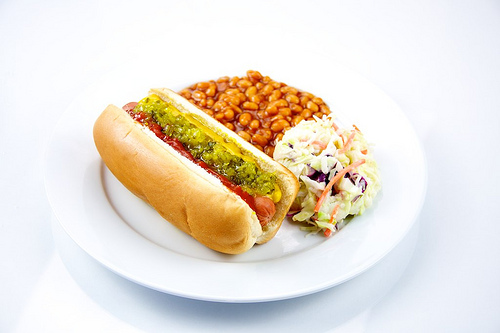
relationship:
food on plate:
[93, 70, 377, 255] [57, 32, 429, 303]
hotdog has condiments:
[92, 85, 299, 255] [135, 94, 282, 201]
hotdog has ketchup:
[92, 85, 299, 255] [134, 112, 255, 207]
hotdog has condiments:
[92, 85, 299, 255] [138, 94, 283, 197]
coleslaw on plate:
[273, 113, 375, 237] [57, 32, 429, 303]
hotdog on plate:
[92, 85, 299, 255] [57, 32, 429, 303]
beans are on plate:
[179, 69, 331, 158] [57, 32, 429, 303]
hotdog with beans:
[92, 85, 299, 255] [179, 69, 331, 158]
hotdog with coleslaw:
[92, 85, 299, 255] [273, 113, 375, 237]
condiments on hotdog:
[138, 94, 283, 197] [92, 85, 299, 255]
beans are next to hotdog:
[179, 69, 331, 158] [92, 85, 299, 255]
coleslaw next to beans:
[273, 113, 375, 237] [179, 69, 331, 158]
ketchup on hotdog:
[134, 112, 255, 207] [92, 85, 299, 255]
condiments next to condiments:
[138, 94, 283, 197] [138, 94, 283, 197]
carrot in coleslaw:
[314, 157, 366, 212] [273, 113, 375, 237]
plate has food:
[57, 32, 429, 303] [93, 70, 377, 255]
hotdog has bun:
[92, 85, 299, 255] [94, 87, 299, 256]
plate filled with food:
[57, 32, 429, 303] [93, 70, 377, 255]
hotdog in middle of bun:
[92, 85, 299, 255] [94, 87, 299, 256]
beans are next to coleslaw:
[179, 69, 331, 158] [273, 113, 375, 237]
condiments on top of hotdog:
[138, 94, 283, 197] [92, 85, 299, 255]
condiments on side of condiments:
[138, 94, 283, 197] [138, 94, 283, 197]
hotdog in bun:
[92, 85, 299, 255] [94, 87, 299, 256]